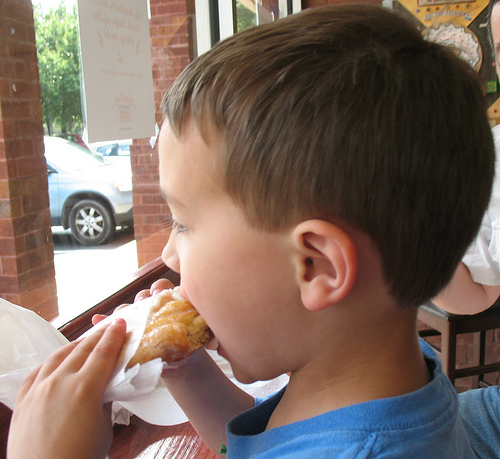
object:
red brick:
[158, 56, 180, 68]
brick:
[134, 204, 162, 214]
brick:
[132, 184, 161, 193]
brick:
[144, 215, 171, 224]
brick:
[134, 215, 143, 225]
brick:
[134, 225, 144, 235]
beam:
[130, 0, 198, 269]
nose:
[162, 232, 180, 273]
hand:
[6, 318, 126, 459]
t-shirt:
[224, 335, 460, 459]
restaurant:
[0, 0, 500, 459]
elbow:
[431, 261, 500, 315]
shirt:
[461, 125, 499, 288]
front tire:
[68, 200, 115, 246]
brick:
[10, 80, 32, 100]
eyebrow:
[159, 187, 188, 212]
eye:
[161, 217, 188, 234]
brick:
[0, 100, 32, 119]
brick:
[14, 119, 44, 138]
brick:
[0, 59, 30, 80]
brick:
[8, 40, 39, 63]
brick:
[0, 137, 35, 161]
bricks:
[0, 158, 19, 180]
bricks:
[4, 284, 50, 309]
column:
[78, 1, 156, 144]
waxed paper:
[0, 295, 190, 427]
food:
[76, 285, 214, 372]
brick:
[17, 155, 47, 178]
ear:
[293, 219, 357, 311]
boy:
[5, 5, 500, 459]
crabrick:
[130, 137, 172, 268]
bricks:
[0, 210, 44, 239]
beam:
[1, 0, 61, 323]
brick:
[157, 2, 196, 15]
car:
[43, 137, 133, 246]